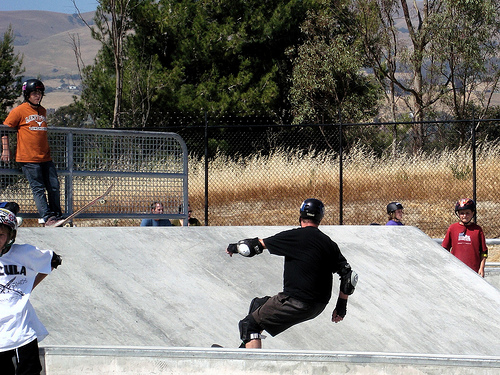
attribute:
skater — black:
[208, 190, 364, 350]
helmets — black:
[293, 195, 332, 234]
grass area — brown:
[192, 144, 496, 196]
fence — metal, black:
[183, 118, 497, 206]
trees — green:
[79, 3, 495, 124]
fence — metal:
[1, 121, 199, 226]